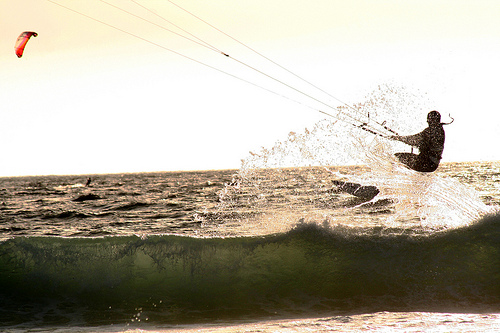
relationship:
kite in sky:
[20, 28, 49, 61] [105, 55, 139, 69]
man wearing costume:
[403, 89, 465, 205] [394, 128, 450, 175]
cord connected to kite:
[190, 35, 299, 104] [20, 28, 49, 61]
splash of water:
[364, 174, 437, 208] [18, 180, 94, 204]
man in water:
[403, 89, 465, 205] [18, 180, 94, 204]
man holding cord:
[403, 89, 465, 205] [190, 35, 299, 104]